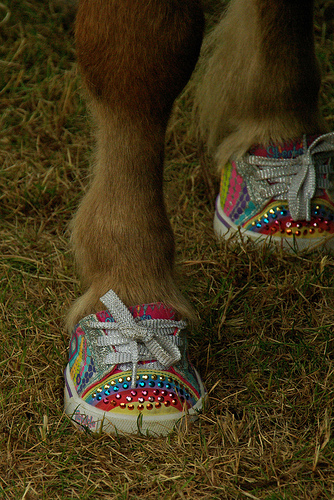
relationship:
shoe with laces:
[214, 131, 334, 256] [84, 290, 187, 380]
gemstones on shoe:
[85, 368, 197, 413] [55, 294, 235, 477]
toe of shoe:
[71, 371, 207, 435] [55, 294, 235, 477]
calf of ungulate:
[80, 76, 176, 263] [53, 0, 333, 435]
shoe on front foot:
[210, 131, 332, 250] [211, 129, 332, 251]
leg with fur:
[215, 8, 303, 149] [216, 37, 289, 114]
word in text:
[266, 143, 305, 157] [264, 144, 302, 159]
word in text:
[71, 405, 97, 428] [68, 405, 94, 427]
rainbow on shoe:
[253, 200, 330, 237] [72, 320, 214, 432]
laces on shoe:
[241, 152, 290, 215] [72, 108, 284, 263]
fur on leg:
[104, 8, 156, 236] [195, 0, 325, 167]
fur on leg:
[104, 8, 156, 236] [64, 0, 201, 330]